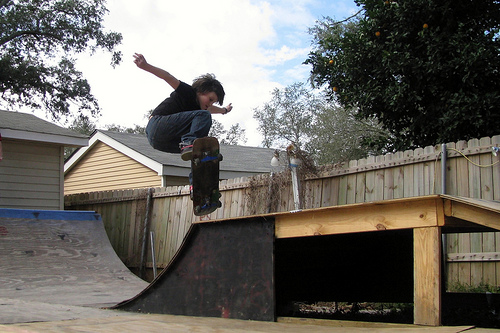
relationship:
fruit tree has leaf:
[302, 0, 500, 153] [325, 96, 333, 103]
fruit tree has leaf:
[302, 0, 500, 153] [363, 115, 368, 119]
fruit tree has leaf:
[302, 0, 500, 153] [376, 116, 383, 123]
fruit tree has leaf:
[302, 0, 500, 153] [400, 132, 406, 140]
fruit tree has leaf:
[302, 0, 500, 153] [393, 49, 398, 55]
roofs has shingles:
[62, 137, 309, 182] [5, 105, 307, 173]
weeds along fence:
[446, 281, 499, 294] [312, 154, 445, 201]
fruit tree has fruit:
[302, 0, 500, 153] [367, 28, 387, 38]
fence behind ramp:
[63, 134, 499, 294] [121, 202, 496, 329]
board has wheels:
[189, 132, 222, 221] [189, 147, 226, 167]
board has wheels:
[189, 132, 222, 221] [195, 196, 222, 212]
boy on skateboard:
[130, 52, 232, 198] [186, 130, 230, 224]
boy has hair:
[130, 52, 232, 198] [193, 73, 225, 107]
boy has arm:
[130, 52, 232, 198] [118, 36, 188, 88]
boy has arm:
[130, 52, 232, 198] [208, 102, 242, 117]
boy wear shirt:
[130, 52, 232, 198] [152, 82, 200, 115]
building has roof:
[116, 72, 496, 292] [64, 122, 314, 179]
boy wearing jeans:
[130, 51, 235, 159] [146, 107, 218, 153]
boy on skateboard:
[130, 52, 232, 198] [182, 132, 228, 219]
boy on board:
[130, 51, 235, 159] [193, 137, 224, 215]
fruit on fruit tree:
[325, 20, 433, 77] [302, 0, 495, 137]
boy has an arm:
[130, 52, 232, 198] [125, 45, 189, 90]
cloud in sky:
[85, 0, 276, 121] [224, 5, 319, 54]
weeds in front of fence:
[444, 267, 499, 311] [63, 131, 484, 295]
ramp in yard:
[0, 197, 500, 332] [277, 289, 484, 327]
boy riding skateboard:
[130, 51, 235, 159] [188, 138, 220, 215]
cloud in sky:
[50, 2, 310, 133] [8, 6, 497, 139]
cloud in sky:
[85, 0, 276, 121] [2, 0, 403, 165]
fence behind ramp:
[104, 137, 496, 270] [0, 197, 500, 332]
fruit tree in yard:
[302, 0, 500, 153] [275, 290, 484, 324]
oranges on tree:
[306, 0, 451, 84] [342, 20, 499, 135]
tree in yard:
[0, 30, 130, 128] [2, 27, 482, 312]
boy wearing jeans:
[130, 52, 232, 198] [145, 110, 212, 185]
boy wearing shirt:
[130, 52, 232, 198] [140, 76, 210, 118]